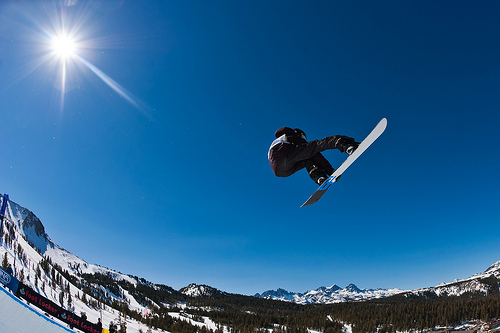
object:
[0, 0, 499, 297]
sky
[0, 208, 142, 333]
ski slope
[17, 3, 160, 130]
ray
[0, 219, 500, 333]
forest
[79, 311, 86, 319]
people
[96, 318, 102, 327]
people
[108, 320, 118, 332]
people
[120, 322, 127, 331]
people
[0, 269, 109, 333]
banner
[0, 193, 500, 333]
hill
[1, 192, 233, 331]
snow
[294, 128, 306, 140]
goggle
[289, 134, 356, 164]
back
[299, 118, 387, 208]
snowboard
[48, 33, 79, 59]
sun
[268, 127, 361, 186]
man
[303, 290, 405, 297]
snow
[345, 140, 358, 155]
feet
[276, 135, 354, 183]
pants